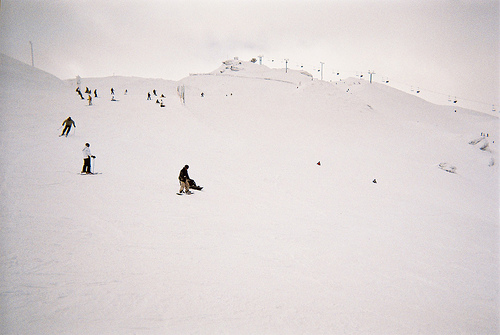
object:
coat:
[81, 146, 94, 160]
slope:
[0, 59, 498, 335]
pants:
[178, 178, 190, 190]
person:
[60, 116, 75, 137]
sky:
[2, 2, 499, 118]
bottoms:
[80, 157, 93, 173]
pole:
[57, 122, 64, 131]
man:
[87, 95, 94, 107]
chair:
[454, 100, 458, 104]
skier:
[146, 92, 152, 100]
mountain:
[1, 55, 498, 333]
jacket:
[178, 167, 189, 184]